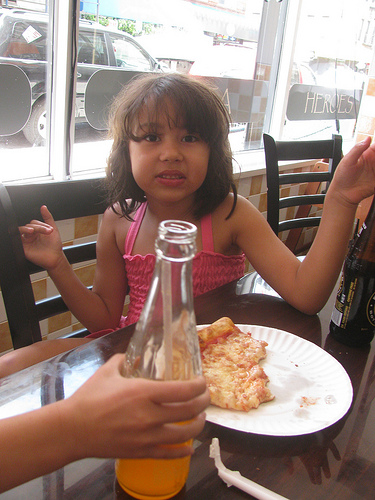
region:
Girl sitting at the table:
[17, 71, 371, 312]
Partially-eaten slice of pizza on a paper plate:
[150, 316, 353, 434]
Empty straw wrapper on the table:
[208, 436, 289, 498]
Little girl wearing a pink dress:
[17, 71, 351, 318]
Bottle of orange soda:
[111, 217, 194, 494]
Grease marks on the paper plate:
[267, 367, 331, 421]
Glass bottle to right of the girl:
[328, 197, 371, 338]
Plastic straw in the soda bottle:
[159, 256, 174, 379]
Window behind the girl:
[69, 0, 289, 170]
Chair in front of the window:
[260, 133, 344, 247]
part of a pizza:
[188, 318, 272, 413]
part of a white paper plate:
[195, 319, 361, 439]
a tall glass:
[113, 218, 213, 499]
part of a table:
[0, 246, 373, 498]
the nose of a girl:
[156, 137, 189, 164]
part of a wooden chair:
[263, 131, 346, 257]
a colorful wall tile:
[233, 176, 269, 215]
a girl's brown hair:
[94, 69, 241, 225]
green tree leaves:
[117, 18, 132, 37]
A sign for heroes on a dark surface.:
[285, 81, 358, 119]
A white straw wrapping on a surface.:
[210, 435, 291, 495]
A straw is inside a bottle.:
[115, 219, 200, 494]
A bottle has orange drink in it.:
[112, 219, 197, 495]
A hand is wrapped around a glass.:
[70, 353, 210, 460]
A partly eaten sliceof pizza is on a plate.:
[155, 314, 352, 434]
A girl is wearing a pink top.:
[16, 76, 373, 331]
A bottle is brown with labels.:
[330, 197, 373, 350]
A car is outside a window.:
[0, 8, 162, 146]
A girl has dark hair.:
[104, 72, 241, 218]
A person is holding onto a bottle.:
[0, 214, 213, 497]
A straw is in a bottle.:
[155, 251, 176, 381]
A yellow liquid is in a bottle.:
[109, 374, 206, 498]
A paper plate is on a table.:
[154, 319, 355, 440]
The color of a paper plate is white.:
[151, 319, 355, 438]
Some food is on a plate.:
[152, 313, 277, 414]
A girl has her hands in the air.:
[12, 68, 373, 332]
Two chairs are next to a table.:
[1, 127, 359, 352]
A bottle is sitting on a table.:
[325, 184, 373, 348]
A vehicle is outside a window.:
[0, 7, 213, 152]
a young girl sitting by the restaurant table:
[25, 75, 373, 327]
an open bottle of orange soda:
[117, 219, 204, 498]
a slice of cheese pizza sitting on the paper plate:
[188, 314, 271, 407]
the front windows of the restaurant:
[0, 1, 374, 148]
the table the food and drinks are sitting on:
[8, 258, 373, 498]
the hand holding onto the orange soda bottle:
[0, 353, 213, 472]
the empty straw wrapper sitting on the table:
[209, 431, 300, 497]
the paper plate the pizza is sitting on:
[180, 318, 354, 438]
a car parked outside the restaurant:
[5, 18, 165, 129]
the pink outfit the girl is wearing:
[117, 194, 246, 315]